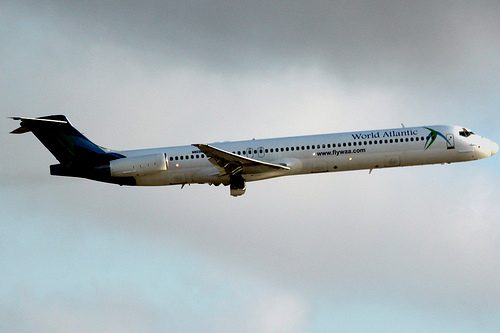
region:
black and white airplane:
[6, 113, 498, 198]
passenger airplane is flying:
[6, 113, 498, 200]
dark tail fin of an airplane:
[6, 113, 111, 186]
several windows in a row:
[141, 134, 439, 162]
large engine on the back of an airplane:
[108, 152, 171, 174]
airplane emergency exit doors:
[244, 144, 266, 159]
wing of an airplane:
[189, 141, 291, 183]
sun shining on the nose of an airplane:
[450, 123, 498, 163]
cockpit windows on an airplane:
[456, 128, 477, 138]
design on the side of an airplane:
[422, 124, 453, 151]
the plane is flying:
[25, 83, 465, 245]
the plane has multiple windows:
[150, 140, 384, 217]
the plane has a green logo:
[424, 94, 493, 191]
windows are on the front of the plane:
[443, 123, 482, 143]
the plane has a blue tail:
[19, 105, 195, 300]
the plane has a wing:
[179, 125, 385, 290]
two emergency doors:
[240, 133, 290, 188]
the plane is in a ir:
[114, 103, 493, 237]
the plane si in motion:
[90, 90, 401, 237]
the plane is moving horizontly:
[96, 127, 469, 181]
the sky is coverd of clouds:
[178, 28, 261, 99]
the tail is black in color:
[26, 101, 107, 190]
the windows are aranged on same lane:
[223, 136, 445, 151]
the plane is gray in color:
[276, 110, 448, 167]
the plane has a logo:
[398, 91, 471, 181]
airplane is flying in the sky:
[6, 113, 498, 195]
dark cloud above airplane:
[38, 2, 498, 101]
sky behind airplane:
[1, 0, 498, 332]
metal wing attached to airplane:
[193, 143, 289, 179]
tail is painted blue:
[8, 114, 109, 175]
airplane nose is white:
[477, 135, 498, 157]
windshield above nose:
[460, 129, 472, 138]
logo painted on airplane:
[423, 126, 453, 153]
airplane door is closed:
[443, 134, 454, 146]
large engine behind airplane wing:
[106, 151, 169, 175]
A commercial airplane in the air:
[3, 97, 496, 217]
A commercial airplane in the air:
[2, 105, 494, 205]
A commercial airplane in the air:
[5, 101, 495, 201]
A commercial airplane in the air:
[0, 101, 495, 201]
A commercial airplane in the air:
[8, 111, 498, 206]